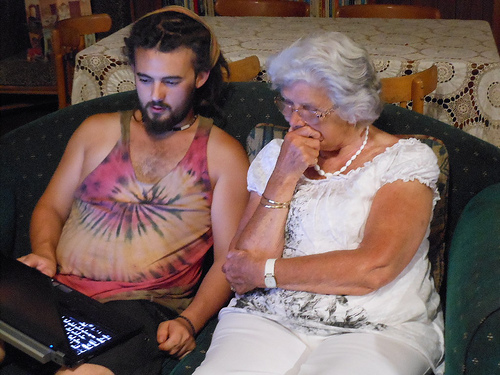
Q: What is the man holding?
A: Laptop.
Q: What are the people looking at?
A: Laptop.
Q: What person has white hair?
A: The old woman.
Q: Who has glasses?
A: The old woman.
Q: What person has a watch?
A: The old woman.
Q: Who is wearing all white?
A: The old woman.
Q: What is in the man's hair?
A: Headband.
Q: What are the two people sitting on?
A: A sofa.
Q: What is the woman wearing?
A: A white shirt and pants.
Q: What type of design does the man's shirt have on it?
A: Tie-dye.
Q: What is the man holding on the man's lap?
A: A laptop.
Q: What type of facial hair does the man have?
A: A mustache and beard.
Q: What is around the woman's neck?
A: A white necklace.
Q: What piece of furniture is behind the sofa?
A: A table.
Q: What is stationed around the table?
A: Chairs.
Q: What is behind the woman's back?
A: A pillow.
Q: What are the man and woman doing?
A: Looking at a laptop.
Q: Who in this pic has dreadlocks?
A: The man.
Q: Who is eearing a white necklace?
A: The woman.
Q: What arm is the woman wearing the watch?
A: Left.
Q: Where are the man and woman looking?
A: At the laptop.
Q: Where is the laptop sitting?
A: On the man's lap.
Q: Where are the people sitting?
A: On a loveseat.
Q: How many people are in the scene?
A: Two.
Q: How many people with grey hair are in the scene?
A: One.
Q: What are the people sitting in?
A: Sofa.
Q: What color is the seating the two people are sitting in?
A: Green.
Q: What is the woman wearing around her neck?
A: Pearls.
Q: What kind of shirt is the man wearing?
A: Tank top.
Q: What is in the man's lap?
A: Laptop.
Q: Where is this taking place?
A: Living room.